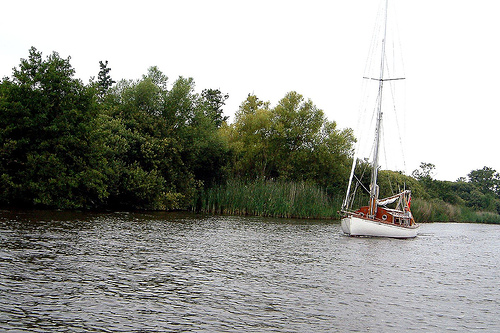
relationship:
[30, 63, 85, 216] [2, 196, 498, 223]
tree along shore line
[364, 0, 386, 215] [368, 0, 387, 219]
wires extending from mast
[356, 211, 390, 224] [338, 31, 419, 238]
windows on boat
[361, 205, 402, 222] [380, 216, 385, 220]
frames of windows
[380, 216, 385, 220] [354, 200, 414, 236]
windows on cabins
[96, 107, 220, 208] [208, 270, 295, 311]
trees growing along river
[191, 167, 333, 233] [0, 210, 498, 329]
grass growing along river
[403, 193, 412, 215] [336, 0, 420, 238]
flag on boat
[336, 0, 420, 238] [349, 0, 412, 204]
boat has mast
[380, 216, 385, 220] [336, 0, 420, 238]
windows on boat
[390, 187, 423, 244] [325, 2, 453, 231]
back of boat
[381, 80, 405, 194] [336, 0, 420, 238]
lines on boat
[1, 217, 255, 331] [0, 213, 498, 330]
ripples in water